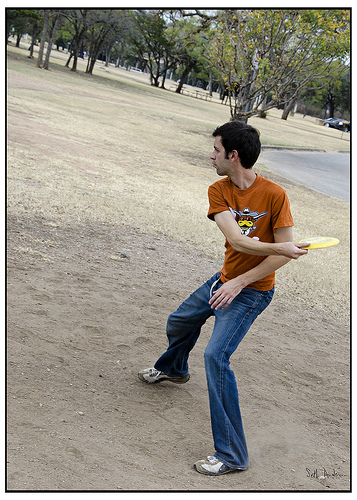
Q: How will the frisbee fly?
A: The man will throw it.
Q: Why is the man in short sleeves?
A: Warm day.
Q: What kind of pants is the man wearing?
A: Denim jeans.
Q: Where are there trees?
A: Background.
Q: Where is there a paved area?
A: Right side.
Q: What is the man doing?
A: He is playing frisbee.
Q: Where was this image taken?
A: At a park.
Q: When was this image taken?
A: During the afternoon.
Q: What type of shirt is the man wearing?
A: A t-shirt.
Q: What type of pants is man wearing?
A: Jeans.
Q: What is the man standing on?
A: Dirt.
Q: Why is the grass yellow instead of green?
A: There has not been enough rain.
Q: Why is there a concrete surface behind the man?
A: It is part of a parking lot.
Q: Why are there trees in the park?
A: To decorate and shade the park.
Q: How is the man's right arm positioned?
A: It is stretched across his chest.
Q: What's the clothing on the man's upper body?
A: Orange shirt.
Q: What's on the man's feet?
A: Shoes.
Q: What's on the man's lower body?
A: Blue jeans.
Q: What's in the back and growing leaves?
A: Trees.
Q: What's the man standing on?
A: Dirt.